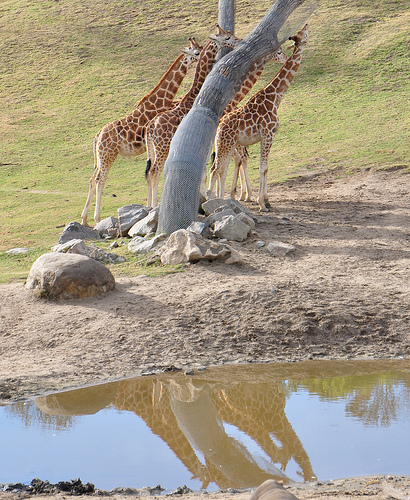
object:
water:
[10, 430, 135, 479]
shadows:
[46, 283, 170, 325]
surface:
[56, 315, 155, 363]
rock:
[19, 242, 117, 303]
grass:
[20, 159, 66, 217]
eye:
[194, 49, 201, 59]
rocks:
[151, 224, 245, 272]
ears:
[178, 48, 194, 57]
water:
[320, 434, 398, 475]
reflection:
[212, 366, 312, 475]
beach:
[174, 273, 394, 305]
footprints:
[266, 303, 326, 353]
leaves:
[181, 27, 265, 193]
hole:
[112, 355, 404, 444]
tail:
[139, 111, 158, 185]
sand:
[121, 276, 177, 321]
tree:
[151, 90, 224, 241]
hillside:
[147, 264, 295, 340]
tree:
[217, 1, 235, 60]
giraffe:
[79, 35, 204, 227]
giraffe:
[141, 23, 246, 213]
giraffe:
[199, 42, 293, 201]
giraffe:
[205, 20, 312, 213]